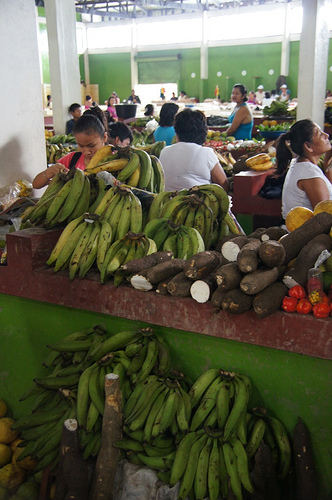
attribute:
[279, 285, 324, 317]
peppers — red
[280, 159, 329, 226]
shirt — white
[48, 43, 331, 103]
wall — green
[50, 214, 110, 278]
bananas — green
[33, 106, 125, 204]
woman — looking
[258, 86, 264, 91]
hat — white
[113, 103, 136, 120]
bucket — black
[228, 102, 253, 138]
top — turquoise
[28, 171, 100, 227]
bananas — green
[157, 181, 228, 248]
bananas — green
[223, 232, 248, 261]
roots — brown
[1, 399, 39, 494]
melons — yellow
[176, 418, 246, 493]
plantains — green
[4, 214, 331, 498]
wall — green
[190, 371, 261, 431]
plantains — green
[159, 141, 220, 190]
shirt — white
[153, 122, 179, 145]
top — blue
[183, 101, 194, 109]
bowl — blue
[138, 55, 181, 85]
door — green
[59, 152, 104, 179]
shirt — pink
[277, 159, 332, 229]
top — white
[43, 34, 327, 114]
walls — green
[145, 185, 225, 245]
banana — green